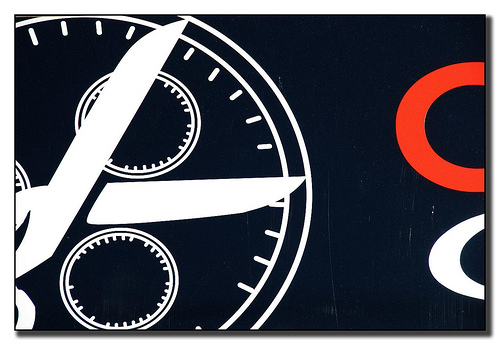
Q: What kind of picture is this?
A: Art.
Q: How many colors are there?
A: 3.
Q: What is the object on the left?
A: Scissors.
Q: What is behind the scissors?
A: Clock.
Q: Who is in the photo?
A: No one.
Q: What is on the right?
A: Loops.